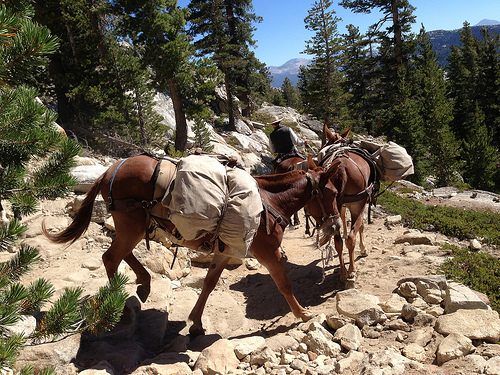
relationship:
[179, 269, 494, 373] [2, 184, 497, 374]
rocks on trail side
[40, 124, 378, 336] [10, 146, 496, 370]
horse over terrain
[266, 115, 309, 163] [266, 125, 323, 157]
man wearing shirt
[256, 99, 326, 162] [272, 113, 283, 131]
man wearing hat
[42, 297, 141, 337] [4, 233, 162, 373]
needles on tree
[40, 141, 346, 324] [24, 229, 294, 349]
horse traveling mountain path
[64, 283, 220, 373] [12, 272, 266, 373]
shadow on ground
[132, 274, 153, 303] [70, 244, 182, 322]
foot off ground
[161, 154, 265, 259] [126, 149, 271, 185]
bag oon back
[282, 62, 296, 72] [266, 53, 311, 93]
sunshine on mountain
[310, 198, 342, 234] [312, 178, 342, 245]
reins on face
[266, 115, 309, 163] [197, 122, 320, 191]
man on horse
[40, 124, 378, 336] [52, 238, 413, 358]
horse on trail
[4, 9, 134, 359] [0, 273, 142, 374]
tree has needles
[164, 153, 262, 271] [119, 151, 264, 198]
bag on back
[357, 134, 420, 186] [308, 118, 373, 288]
bag on horse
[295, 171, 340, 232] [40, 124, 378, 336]
harness on horse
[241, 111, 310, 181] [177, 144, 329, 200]
arm rides on horse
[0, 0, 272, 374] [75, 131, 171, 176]
tree on ground